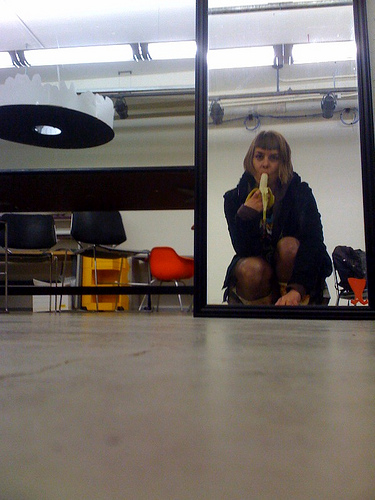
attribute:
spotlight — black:
[311, 79, 347, 123]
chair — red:
[147, 244, 193, 286]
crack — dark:
[0, 344, 147, 382]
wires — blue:
[209, 102, 362, 133]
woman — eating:
[221, 129, 332, 306]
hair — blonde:
[242, 130, 293, 184]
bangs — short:
[256, 136, 279, 149]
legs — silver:
[135, 283, 175, 323]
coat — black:
[218, 165, 335, 306]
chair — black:
[65, 208, 156, 316]